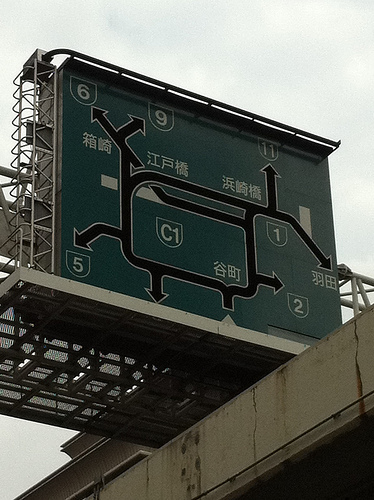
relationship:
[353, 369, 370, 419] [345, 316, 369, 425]
rust in crack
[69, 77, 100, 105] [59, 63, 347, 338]
6 on sign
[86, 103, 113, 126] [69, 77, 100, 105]
arrows are pointing to 6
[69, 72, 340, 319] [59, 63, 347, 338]
characters on sign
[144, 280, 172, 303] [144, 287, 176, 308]
arrow pointing down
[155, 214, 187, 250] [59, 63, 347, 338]
c1 on sign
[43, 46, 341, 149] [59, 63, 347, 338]
bar across top of traffic sign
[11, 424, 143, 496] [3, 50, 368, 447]
building behind sign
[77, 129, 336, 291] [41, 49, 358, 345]
foreign writing on sign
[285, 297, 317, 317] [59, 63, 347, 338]
number on billboard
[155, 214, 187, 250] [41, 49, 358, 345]
c1 on sign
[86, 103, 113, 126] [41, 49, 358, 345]
arrows are on sign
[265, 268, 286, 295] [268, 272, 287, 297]
arrow pointing right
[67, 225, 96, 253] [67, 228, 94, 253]
arrow pointing left